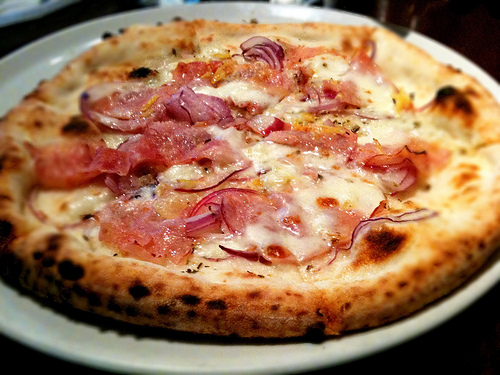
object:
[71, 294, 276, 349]
shadow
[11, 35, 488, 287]
cheese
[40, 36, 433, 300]
pizza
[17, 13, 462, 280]
pizza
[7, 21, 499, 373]
pizza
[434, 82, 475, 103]
crust spot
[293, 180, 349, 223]
ground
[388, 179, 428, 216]
ground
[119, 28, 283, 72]
pizza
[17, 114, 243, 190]
bacon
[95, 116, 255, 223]
ham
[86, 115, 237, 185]
meat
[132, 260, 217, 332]
crust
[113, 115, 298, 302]
pizza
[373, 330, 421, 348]
plate part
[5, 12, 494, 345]
pizza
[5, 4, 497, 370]
plate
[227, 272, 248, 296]
pizza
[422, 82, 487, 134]
burned cheese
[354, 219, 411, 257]
burned cheese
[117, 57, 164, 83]
burned cheese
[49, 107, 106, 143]
burned cheese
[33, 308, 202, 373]
white plate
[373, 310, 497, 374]
dark counter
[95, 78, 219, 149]
ham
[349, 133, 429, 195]
ham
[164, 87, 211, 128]
ham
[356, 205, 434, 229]
onion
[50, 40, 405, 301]
pizza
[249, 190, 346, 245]
cheese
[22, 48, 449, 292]
pizza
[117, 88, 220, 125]
ham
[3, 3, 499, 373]
tray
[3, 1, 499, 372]
table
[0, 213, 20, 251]
spot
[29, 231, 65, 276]
spot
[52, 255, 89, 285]
spot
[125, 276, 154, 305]
spot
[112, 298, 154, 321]
spot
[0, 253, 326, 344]
crust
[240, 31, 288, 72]
onion clump